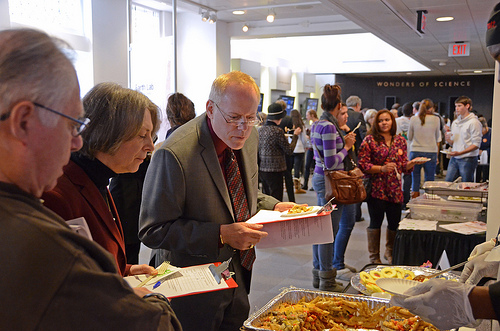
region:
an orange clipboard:
[122, 250, 247, 302]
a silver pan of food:
[229, 284, 437, 329]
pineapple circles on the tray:
[349, 260, 455, 300]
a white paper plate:
[375, 273, 434, 303]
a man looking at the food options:
[157, 61, 286, 328]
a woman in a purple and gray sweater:
[306, 114, 356, 192]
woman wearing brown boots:
[358, 220, 397, 261]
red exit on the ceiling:
[444, 36, 476, 61]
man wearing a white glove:
[405, 278, 480, 328]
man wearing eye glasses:
[0, 23, 125, 327]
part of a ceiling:
[321, 13, 376, 43]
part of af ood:
[314, 283, 345, 319]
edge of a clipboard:
[203, 273, 224, 302]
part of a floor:
[284, 250, 304, 277]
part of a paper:
[186, 263, 233, 292]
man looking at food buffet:
[134, 46, 348, 271]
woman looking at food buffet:
[61, 69, 187, 235]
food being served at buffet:
[252, 217, 499, 328]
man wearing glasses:
[0, 12, 103, 204]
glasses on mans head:
[1, 90, 94, 134]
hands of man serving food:
[376, 213, 499, 328]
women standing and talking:
[311, 70, 413, 215]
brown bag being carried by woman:
[318, 161, 370, 211]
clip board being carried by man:
[117, 244, 251, 309]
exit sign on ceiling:
[435, 32, 477, 61]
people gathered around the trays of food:
[8, 49, 443, 326]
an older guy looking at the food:
[175, 69, 348, 329]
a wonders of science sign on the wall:
[371, 76, 476, 90]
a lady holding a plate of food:
[361, 107, 433, 243]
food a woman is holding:
[409, 153, 431, 165]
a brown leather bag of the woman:
[321, 164, 367, 204]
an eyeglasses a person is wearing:
[221, 113, 266, 129]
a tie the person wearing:
[221, 157, 249, 211]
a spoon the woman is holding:
[351, 120, 362, 137]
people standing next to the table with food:
[311, 82, 438, 263]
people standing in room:
[3, 66, 473, 316]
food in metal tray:
[245, 284, 420, 329]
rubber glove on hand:
[400, 279, 475, 327]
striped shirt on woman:
[312, 117, 342, 176]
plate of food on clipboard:
[246, 199, 333, 224]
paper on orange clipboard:
[136, 257, 239, 295]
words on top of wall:
[371, 71, 474, 93]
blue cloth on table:
[388, 228, 483, 270]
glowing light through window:
[125, 5, 173, 104]